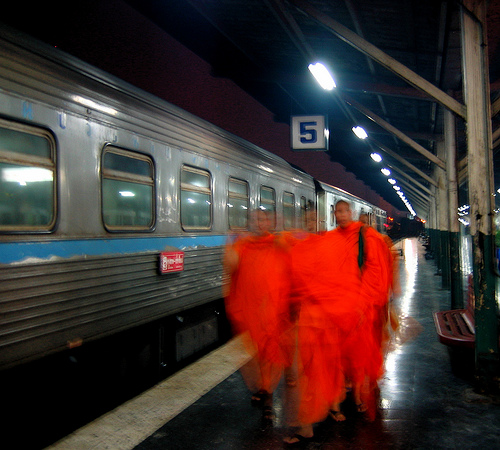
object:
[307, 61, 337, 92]
light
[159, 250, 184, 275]
sign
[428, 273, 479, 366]
bench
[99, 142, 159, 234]
window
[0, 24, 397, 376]
train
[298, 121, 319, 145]
number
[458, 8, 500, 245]
pole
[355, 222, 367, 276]
strap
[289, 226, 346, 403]
gown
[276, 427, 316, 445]
flip flop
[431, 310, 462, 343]
slits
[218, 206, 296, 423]
man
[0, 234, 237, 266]
strip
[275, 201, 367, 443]
monks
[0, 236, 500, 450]
platform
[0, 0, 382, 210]
sky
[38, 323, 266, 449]
line